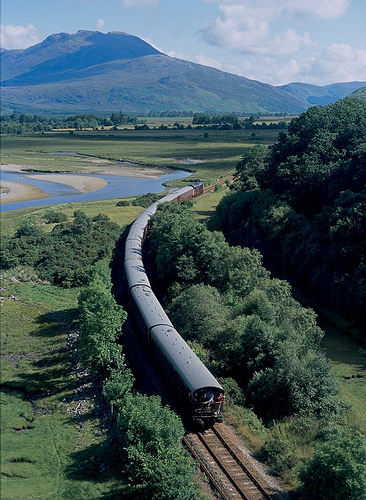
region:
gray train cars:
[110, 194, 223, 423]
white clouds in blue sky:
[193, 40, 223, 56]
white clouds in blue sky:
[311, 17, 341, 32]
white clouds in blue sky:
[263, 31, 293, 54]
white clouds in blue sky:
[210, 24, 252, 49]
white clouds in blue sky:
[154, 16, 195, 54]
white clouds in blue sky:
[294, 13, 333, 42]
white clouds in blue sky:
[290, 34, 327, 60]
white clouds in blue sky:
[240, 20, 282, 70]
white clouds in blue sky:
[180, 9, 230, 29]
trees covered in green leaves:
[205, 266, 278, 357]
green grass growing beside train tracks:
[33, 432, 64, 486]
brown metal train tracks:
[206, 441, 238, 466]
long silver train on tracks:
[122, 178, 231, 414]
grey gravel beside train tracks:
[252, 457, 266, 474]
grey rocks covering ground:
[54, 368, 94, 424]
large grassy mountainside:
[32, 26, 185, 116]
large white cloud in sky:
[184, 0, 353, 51]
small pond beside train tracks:
[1, 135, 198, 241]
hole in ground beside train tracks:
[13, 374, 56, 427]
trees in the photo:
[262, 149, 339, 220]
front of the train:
[158, 350, 260, 434]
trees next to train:
[101, 378, 180, 470]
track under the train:
[181, 432, 248, 482]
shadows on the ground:
[31, 328, 84, 432]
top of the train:
[118, 242, 157, 307]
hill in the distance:
[17, 20, 178, 101]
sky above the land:
[177, 1, 286, 52]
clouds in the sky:
[206, 1, 314, 51]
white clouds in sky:
[188, 7, 286, 66]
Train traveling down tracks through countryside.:
[124, 181, 223, 425]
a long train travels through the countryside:
[99, 169, 223, 418]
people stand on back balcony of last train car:
[186, 383, 211, 408]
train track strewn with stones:
[172, 428, 218, 480]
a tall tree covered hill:
[0, 18, 351, 107]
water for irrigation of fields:
[0, 158, 197, 213]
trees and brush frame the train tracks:
[103, 199, 326, 441]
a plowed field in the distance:
[143, 118, 290, 127]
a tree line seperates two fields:
[57, 123, 295, 127]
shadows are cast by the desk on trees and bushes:
[0, 295, 118, 498]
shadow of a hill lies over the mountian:
[9, 31, 159, 84]